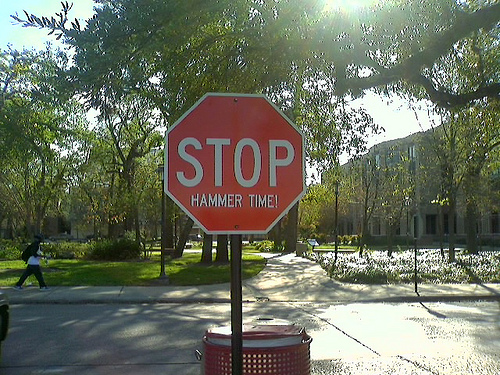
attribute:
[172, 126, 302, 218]
saying — stop hammer time, funny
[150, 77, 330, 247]
sign — stop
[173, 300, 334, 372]
can — trash, red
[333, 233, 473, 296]
garden — flower, white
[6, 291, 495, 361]
roadway — thin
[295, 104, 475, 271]
buildings — multistory, tall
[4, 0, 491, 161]
branches — green, leafy, overhanging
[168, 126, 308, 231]
catchphrase — mc hammer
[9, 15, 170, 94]
branch — large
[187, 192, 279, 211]
words — hammer time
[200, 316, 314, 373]
trash bin — red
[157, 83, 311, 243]
sign — red, stop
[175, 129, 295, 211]
writing — white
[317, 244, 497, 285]
flowers — white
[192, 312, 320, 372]
container — trash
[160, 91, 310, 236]
sign — stop, red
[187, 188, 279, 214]
saying — funny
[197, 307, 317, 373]
can — garbage, red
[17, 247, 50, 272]
shirt — white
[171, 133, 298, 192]
writing — white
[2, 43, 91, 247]
trees — green, tall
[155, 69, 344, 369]
sign — red, white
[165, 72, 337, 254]
words — bold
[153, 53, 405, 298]
sign — rectangular, red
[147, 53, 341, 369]
sign — red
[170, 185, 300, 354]
post — black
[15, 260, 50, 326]
pants — black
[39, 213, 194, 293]
grass — green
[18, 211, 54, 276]
shirt — white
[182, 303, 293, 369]
container — red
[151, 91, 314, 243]
stop sign — red